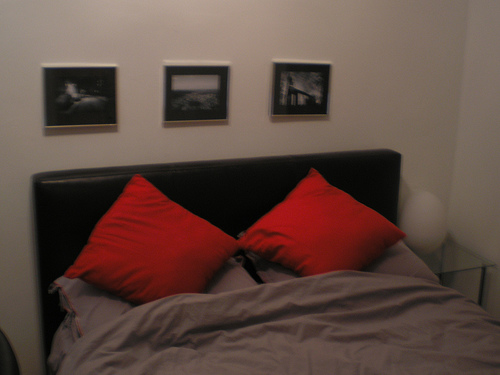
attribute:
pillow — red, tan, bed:
[42, 161, 246, 282]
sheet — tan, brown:
[58, 250, 420, 347]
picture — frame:
[15, 44, 340, 150]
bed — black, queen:
[110, 160, 495, 358]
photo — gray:
[12, 53, 101, 132]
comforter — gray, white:
[70, 228, 253, 333]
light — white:
[343, 181, 477, 250]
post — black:
[7, 173, 66, 288]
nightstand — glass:
[408, 213, 483, 288]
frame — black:
[3, 27, 437, 327]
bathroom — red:
[115, 37, 459, 237]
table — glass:
[394, 216, 499, 303]